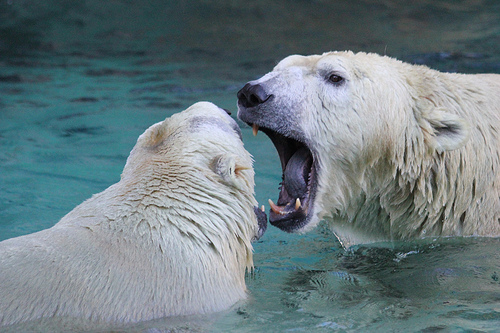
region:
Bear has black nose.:
[237, 84, 267, 121]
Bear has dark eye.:
[317, 63, 345, 93]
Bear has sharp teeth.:
[262, 193, 310, 217]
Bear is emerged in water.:
[322, 208, 472, 284]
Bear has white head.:
[349, 46, 434, 88]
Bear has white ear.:
[426, 100, 464, 147]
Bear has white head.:
[148, 116, 183, 145]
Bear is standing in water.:
[162, 235, 273, 315]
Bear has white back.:
[1, 243, 100, 276]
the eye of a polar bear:
[325, 69, 352, 87]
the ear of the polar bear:
[420, 110, 471, 152]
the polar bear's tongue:
[280, 148, 312, 195]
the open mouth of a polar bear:
[235, 110, 317, 227]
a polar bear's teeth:
[267, 195, 303, 215]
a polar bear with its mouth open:
[238, 52, 498, 242]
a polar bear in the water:
[0, 97, 254, 329]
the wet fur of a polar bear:
[369, 73, 499, 237]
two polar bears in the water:
[2, 56, 496, 330]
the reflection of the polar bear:
[278, 247, 406, 321]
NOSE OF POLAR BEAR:
[231, 79, 274, 114]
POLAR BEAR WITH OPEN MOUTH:
[229, 39, 496, 261]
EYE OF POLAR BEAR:
[312, 61, 356, 93]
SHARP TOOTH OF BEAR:
[290, 191, 304, 213]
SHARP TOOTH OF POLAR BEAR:
[260, 194, 282, 216]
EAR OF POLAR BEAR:
[416, 96, 470, 151]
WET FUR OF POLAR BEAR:
[388, 168, 451, 215]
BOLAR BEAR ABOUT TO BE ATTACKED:
[3, 87, 257, 324]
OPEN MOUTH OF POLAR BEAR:
[236, 114, 325, 239]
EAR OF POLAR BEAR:
[139, 118, 182, 155]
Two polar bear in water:
[30, 39, 475, 326]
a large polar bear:
[235, 34, 497, 264]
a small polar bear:
[15, 82, 271, 331]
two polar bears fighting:
[4, 43, 490, 318]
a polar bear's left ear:
[418, 100, 478, 190]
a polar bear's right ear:
[215, 146, 252, 201]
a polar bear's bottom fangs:
[260, 190, 310, 219]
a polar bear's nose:
[237, 77, 284, 105]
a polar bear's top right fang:
[242, 119, 277, 143]